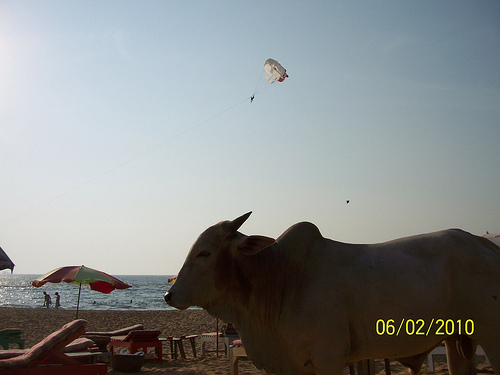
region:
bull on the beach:
[182, 209, 425, 361]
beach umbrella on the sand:
[46, 239, 133, 330]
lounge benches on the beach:
[82, 317, 160, 366]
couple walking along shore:
[36, 281, 70, 314]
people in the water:
[90, 295, 143, 309]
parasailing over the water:
[244, 55, 320, 118]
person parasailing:
[215, 88, 281, 119]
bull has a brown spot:
[211, 199, 299, 301]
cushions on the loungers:
[1, 313, 159, 359]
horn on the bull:
[218, 193, 283, 243]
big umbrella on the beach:
[28, 257, 120, 320]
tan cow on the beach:
[164, 208, 497, 370]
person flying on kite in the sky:
[235, 57, 293, 108]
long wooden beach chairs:
[5, 326, 170, 368]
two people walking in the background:
[36, 287, 68, 311]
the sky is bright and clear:
[2, 7, 179, 238]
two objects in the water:
[86, 294, 141, 307]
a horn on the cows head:
[226, 200, 257, 233]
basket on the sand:
[108, 350, 152, 372]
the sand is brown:
[92, 308, 172, 326]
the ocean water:
[130, 276, 157, 306]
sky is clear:
[339, 73, 476, 179]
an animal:
[172, 240, 468, 353]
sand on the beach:
[118, 304, 172, 326]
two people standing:
[34, 287, 71, 312]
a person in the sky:
[246, 92, 268, 114]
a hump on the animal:
[281, 214, 326, 247]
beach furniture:
[21, 317, 99, 364]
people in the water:
[89, 293, 141, 305]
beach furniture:
[110, 320, 222, 350]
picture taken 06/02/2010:
[367, 299, 496, 362]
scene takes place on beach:
[0, 22, 474, 371]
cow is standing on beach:
[149, 197, 498, 373]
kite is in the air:
[210, 29, 327, 127]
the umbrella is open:
[10, 241, 157, 331]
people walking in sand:
[33, 288, 73, 320]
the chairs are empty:
[5, 287, 172, 368]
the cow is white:
[149, 199, 484, 356]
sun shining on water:
[0, 263, 62, 313]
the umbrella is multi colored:
[38, 254, 145, 310]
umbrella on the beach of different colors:
[31, 242, 135, 311]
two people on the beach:
[36, 284, 62, 316]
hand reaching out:
[32, 312, 120, 372]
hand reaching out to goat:
[2, 210, 496, 368]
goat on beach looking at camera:
[168, 199, 497, 371]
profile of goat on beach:
[156, 194, 261, 336]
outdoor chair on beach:
[120, 330, 165, 364]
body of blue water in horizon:
[0, 263, 171, 305]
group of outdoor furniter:
[86, 319, 246, 358]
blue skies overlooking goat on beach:
[2, 5, 498, 358]